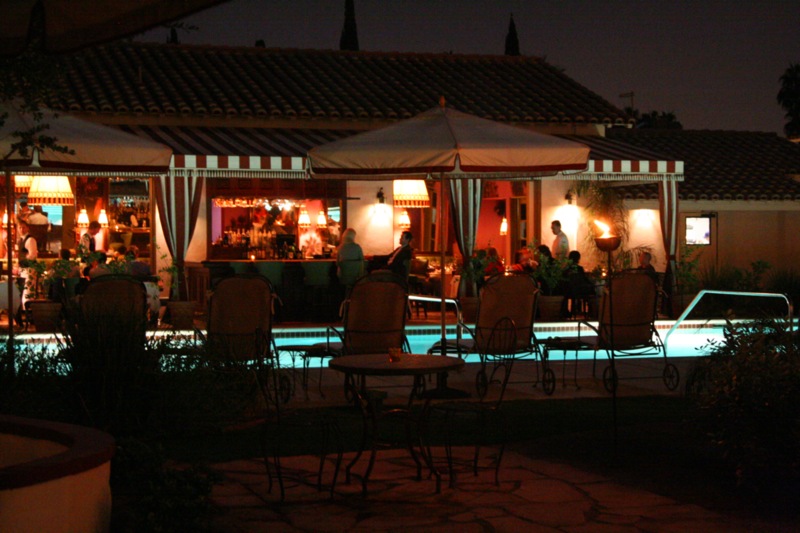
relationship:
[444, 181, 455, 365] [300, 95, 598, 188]
pole with umbrella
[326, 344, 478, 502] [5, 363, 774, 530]
table on deck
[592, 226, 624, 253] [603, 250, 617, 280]
torch on pole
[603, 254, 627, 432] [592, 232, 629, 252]
pole with torch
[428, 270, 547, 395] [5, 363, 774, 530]
chair on top of deck